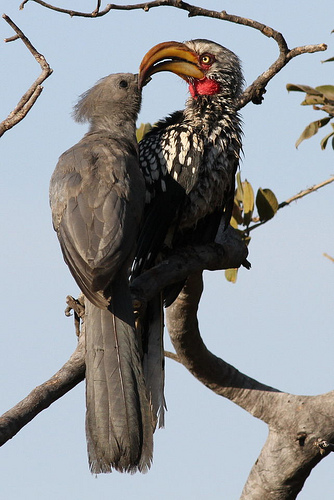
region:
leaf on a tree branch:
[244, 176, 286, 226]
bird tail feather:
[65, 298, 161, 480]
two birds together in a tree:
[45, 34, 243, 473]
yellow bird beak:
[132, 32, 199, 86]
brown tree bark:
[217, 344, 328, 467]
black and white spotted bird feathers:
[149, 121, 223, 217]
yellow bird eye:
[192, 47, 216, 66]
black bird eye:
[108, 72, 128, 92]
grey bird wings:
[43, 128, 143, 308]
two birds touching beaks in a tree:
[67, 35, 242, 125]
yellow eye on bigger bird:
[201, 55, 210, 63]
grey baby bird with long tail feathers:
[46, 70, 155, 473]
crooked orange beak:
[136, 40, 204, 90]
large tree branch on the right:
[163, 270, 330, 498]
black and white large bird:
[134, 37, 237, 423]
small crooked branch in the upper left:
[0, 14, 52, 136]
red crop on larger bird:
[187, 77, 218, 98]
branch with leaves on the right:
[211, 83, 333, 281]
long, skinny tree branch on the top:
[20, 1, 327, 105]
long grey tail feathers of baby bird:
[80, 271, 153, 472]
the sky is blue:
[68, 33, 148, 60]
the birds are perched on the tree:
[58, 50, 239, 277]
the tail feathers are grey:
[82, 356, 156, 460]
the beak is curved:
[130, 27, 220, 84]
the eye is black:
[100, 69, 143, 95]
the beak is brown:
[141, 40, 206, 87]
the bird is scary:
[141, 42, 274, 231]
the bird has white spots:
[157, 116, 260, 214]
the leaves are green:
[249, 166, 289, 221]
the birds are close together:
[74, 39, 250, 284]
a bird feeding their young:
[57, 30, 256, 143]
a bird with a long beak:
[131, 24, 248, 104]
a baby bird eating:
[57, 43, 153, 142]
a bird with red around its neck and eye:
[157, 25, 268, 101]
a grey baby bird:
[37, 56, 164, 252]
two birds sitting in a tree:
[4, 26, 258, 485]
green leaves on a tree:
[206, 146, 323, 260]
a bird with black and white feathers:
[128, 41, 259, 213]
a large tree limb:
[213, 364, 333, 499]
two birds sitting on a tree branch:
[0, 32, 259, 399]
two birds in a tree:
[9, 16, 293, 479]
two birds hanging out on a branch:
[37, 36, 266, 480]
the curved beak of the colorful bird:
[134, 36, 205, 92]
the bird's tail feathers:
[75, 277, 191, 486]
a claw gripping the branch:
[60, 286, 82, 326]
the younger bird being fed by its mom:
[42, 68, 153, 322]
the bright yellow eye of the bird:
[193, 47, 218, 70]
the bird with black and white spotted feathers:
[133, 25, 258, 334]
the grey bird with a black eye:
[31, 65, 156, 474]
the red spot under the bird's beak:
[185, 77, 221, 106]